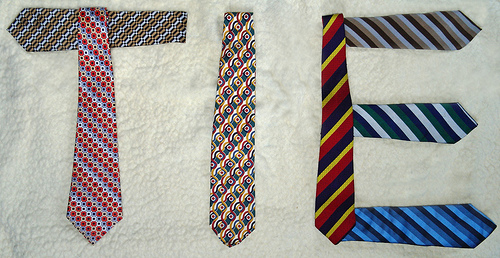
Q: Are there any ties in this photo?
A: Yes, there is a tie.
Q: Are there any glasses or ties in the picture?
A: Yes, there is a tie.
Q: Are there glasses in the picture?
A: No, there are no glasses.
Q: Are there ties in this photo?
A: Yes, there is a tie.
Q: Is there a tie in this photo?
A: Yes, there is a tie.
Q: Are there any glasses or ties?
A: Yes, there is a tie.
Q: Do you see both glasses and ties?
A: No, there is a tie but no glasses.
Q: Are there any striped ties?
A: Yes, there is a striped tie.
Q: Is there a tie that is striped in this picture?
A: Yes, there is a striped tie.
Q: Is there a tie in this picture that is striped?
A: Yes, there is a tie that is striped.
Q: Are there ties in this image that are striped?
A: Yes, there is a tie that is striped.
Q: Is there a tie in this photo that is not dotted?
A: Yes, there is a striped tie.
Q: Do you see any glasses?
A: No, there are no glasses.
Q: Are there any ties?
A: Yes, there is a tie.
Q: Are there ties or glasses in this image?
A: Yes, there is a tie.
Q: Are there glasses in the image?
A: No, there are no glasses.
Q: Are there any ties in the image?
A: Yes, there is a tie.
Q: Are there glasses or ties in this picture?
A: Yes, there is a tie.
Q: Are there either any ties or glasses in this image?
A: Yes, there is a tie.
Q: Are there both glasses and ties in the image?
A: No, there is a tie but no glasses.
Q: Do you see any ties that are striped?
A: Yes, there is a striped tie.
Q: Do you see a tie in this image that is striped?
A: Yes, there is a tie that is striped.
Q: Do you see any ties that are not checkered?
A: Yes, there is a striped tie.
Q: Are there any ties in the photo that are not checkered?
A: Yes, there is a striped tie.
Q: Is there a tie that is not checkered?
A: Yes, there is a striped tie.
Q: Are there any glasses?
A: No, there are no glasses.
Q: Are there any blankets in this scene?
A: Yes, there is a blanket.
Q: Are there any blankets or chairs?
A: Yes, there is a blanket.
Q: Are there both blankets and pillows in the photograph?
A: No, there is a blanket but no pillows.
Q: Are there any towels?
A: No, there are no towels.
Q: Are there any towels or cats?
A: No, there are no towels or cats.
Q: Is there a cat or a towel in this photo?
A: No, there are no towels or cats.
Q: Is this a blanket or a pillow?
A: This is a blanket.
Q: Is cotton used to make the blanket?
A: Yes, the blanket is made of cotton.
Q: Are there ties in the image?
A: Yes, there is a tie.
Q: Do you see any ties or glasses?
A: Yes, there is a tie.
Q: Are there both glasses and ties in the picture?
A: No, there is a tie but no glasses.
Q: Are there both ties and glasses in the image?
A: No, there is a tie but no glasses.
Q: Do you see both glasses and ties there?
A: No, there is a tie but no glasses.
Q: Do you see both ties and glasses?
A: No, there is a tie but no glasses.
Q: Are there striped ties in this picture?
A: Yes, there is a striped tie.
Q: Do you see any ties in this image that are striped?
A: Yes, there is a tie that is striped.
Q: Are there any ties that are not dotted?
A: Yes, there is a striped tie.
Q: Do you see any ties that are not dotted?
A: Yes, there is a striped tie.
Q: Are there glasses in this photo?
A: No, there are no glasses.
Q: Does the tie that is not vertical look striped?
A: Yes, the tie is striped.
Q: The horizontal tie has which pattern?
A: The tie is striped.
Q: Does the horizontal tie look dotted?
A: No, the tie is striped.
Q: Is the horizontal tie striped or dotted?
A: The necktie is striped.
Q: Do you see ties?
A: Yes, there is a tie.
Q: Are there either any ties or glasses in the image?
A: Yes, there is a tie.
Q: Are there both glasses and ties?
A: No, there is a tie but no glasses.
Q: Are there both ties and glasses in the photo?
A: No, there is a tie but no glasses.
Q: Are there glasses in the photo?
A: No, there are no glasses.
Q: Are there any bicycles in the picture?
A: No, there are no bicycles.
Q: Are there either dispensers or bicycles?
A: No, there are no bicycles or dispensers.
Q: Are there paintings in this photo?
A: No, there are no paintings.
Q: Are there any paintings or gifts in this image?
A: No, there are no paintings or gifts.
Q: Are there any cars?
A: No, there are no cars.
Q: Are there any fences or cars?
A: No, there are no cars or fences.